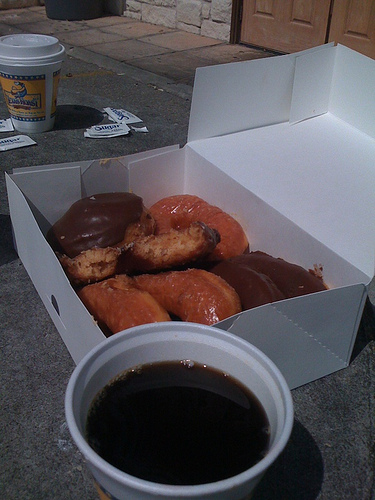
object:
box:
[4, 39, 374, 389]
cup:
[64, 320, 294, 495]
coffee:
[86, 360, 269, 486]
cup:
[0, 34, 66, 133]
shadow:
[49, 104, 104, 130]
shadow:
[245, 413, 323, 499]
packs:
[82, 106, 148, 138]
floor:
[0, 1, 374, 500]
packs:
[0, 117, 38, 151]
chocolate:
[46, 190, 142, 257]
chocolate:
[209, 250, 325, 310]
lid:
[1, 34, 66, 67]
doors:
[238, 1, 373, 56]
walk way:
[1, 1, 290, 99]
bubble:
[181, 357, 194, 372]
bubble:
[113, 371, 130, 383]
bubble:
[261, 422, 271, 435]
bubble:
[84, 385, 107, 416]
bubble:
[88, 434, 94, 447]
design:
[0, 69, 47, 123]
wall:
[94, 0, 231, 41]